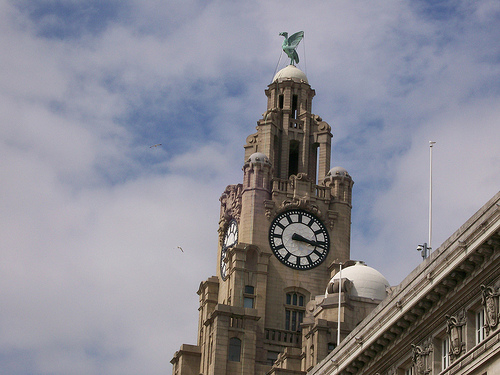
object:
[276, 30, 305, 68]
statue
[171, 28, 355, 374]
clock tower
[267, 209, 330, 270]
clock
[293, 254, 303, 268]
roman numerals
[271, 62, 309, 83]
dome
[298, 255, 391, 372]
building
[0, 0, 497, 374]
sky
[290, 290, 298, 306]
window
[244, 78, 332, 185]
pillars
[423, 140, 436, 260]
lightning rod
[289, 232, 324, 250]
hand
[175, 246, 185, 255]
bird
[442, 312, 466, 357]
statues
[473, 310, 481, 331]
windows